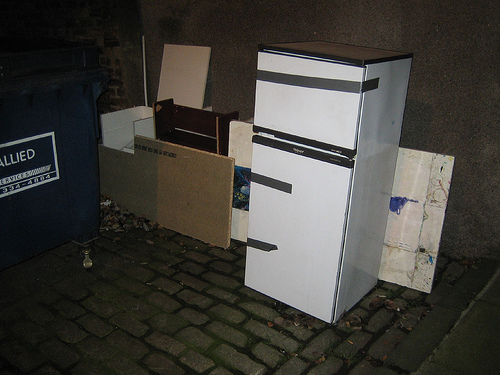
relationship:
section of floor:
[35, 228, 266, 375] [1, 213, 499, 373]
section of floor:
[35, 228, 266, 375] [0, 190, 500, 372]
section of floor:
[266, 326, 402, 373] [0, 190, 500, 372]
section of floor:
[401, 295, 499, 372] [0, 190, 500, 372]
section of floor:
[95, 244, 258, 345] [0, 190, 500, 372]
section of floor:
[95, 255, 265, 367] [0, 190, 500, 372]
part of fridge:
[244, 213, 388, 289] [240, 35, 417, 325]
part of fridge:
[244, 123, 402, 256] [240, 35, 417, 325]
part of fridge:
[244, 123, 398, 256] [240, 35, 417, 325]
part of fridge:
[250, 37, 416, 148] [240, 35, 417, 325]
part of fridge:
[241, 235, 386, 327] [240, 35, 417, 325]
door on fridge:
[244, 42, 364, 325] [240, 35, 417, 325]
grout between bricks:
[252, 335, 262, 340] [8, 222, 338, 367]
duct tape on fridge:
[259, 128, 268, 138] [240, 35, 417, 325]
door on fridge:
[242, 51, 365, 325] [240, 35, 417, 325]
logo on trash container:
[0, 128, 61, 208] [1, 40, 104, 269]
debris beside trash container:
[97, 39, 458, 324] [1, 40, 104, 269]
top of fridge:
[261, 35, 417, 65] [240, 35, 417, 325]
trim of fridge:
[257, 37, 413, 64] [240, 35, 417, 325]